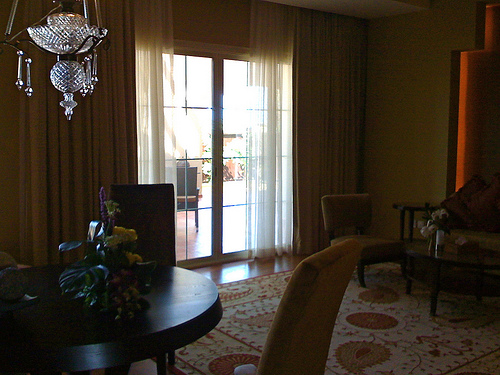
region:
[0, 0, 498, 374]
nicely decorated living area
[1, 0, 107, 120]
beautiful clear crystal chandelier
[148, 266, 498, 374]
large goldtone rug on floor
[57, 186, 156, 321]
floral arrangement on table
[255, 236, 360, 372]
high back upholstered chair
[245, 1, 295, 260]
cream colored sheer panel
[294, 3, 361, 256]
goldtone floor-to-ceiling drapery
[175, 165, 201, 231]
chair in outdoor area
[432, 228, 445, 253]
white candle on coffee table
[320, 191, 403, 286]
low back upholstered chair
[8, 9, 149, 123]
the chandler is crystal clear in color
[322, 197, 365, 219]
the chair is oliver color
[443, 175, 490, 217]
the pillows are brown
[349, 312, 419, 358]
the rug is white and brown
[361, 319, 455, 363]
the rug has decorative designs on it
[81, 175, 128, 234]
the flower is purple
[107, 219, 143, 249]
the flower is yellow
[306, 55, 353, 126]
the curtain is oliver in color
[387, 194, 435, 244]
the stand is dark brown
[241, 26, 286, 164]
the shear is white in color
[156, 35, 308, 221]
window above the ground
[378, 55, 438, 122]
wall next to window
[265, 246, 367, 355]
chair on the ground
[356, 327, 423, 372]
rug on the ground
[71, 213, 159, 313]
plant on the table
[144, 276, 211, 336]
round table next to chair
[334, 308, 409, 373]
design on carpet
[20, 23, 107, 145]
chandelier above the table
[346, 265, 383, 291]
leg of the chair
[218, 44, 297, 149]
curtains next to window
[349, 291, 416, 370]
the carpet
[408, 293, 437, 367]
the carpet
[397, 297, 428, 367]
the carpet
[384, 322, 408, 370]
the carpet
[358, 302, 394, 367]
the carpet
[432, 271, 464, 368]
the carpet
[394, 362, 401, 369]
the carpet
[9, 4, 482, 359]
A living room scene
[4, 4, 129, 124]
A light fixture is hanging from the ceiling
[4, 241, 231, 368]
A round table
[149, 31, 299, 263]
This is a glass door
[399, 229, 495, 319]
A coffee table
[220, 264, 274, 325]
A rug is covering the floor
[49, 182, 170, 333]
A flower arrangement is on the table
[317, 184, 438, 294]
A chair is next to the table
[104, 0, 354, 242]
Curtains are partially covering the windows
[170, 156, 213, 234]
A chair is sitting outside